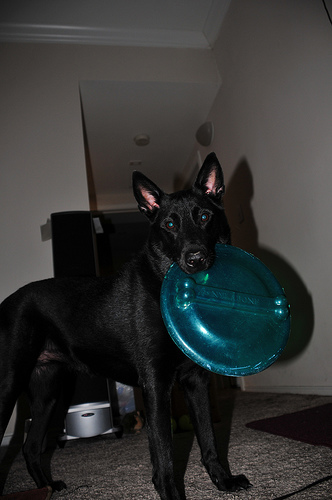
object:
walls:
[0, 0, 116, 290]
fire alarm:
[134, 134, 150, 147]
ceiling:
[78, 82, 223, 213]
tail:
[2, 404, 26, 493]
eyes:
[167, 220, 175, 228]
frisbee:
[160, 243, 292, 376]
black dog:
[0, 151, 253, 500]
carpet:
[245, 404, 332, 447]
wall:
[214, 5, 332, 393]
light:
[195, 121, 214, 147]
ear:
[132, 170, 164, 224]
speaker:
[40, 210, 136, 277]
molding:
[0, 22, 208, 47]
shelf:
[62, 380, 135, 432]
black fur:
[82, 277, 153, 360]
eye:
[201, 213, 209, 222]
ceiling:
[0, 0, 227, 49]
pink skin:
[205, 170, 223, 194]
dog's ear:
[192, 152, 226, 200]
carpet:
[254, 449, 304, 488]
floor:
[0, 396, 332, 500]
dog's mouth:
[173, 243, 214, 274]